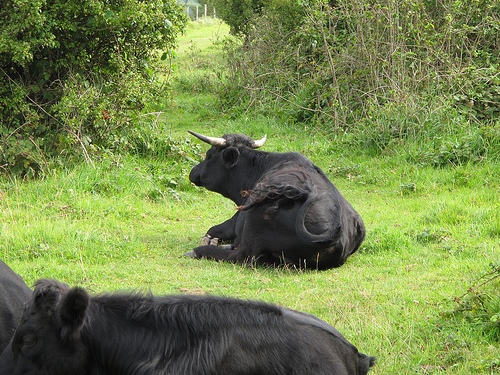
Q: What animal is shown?
A: Cow.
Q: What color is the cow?
A: Black.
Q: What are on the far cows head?
A: Horns.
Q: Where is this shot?
A: Pasture.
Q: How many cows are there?
A: 2.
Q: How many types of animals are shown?
A: 1.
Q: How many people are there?
A: 0.